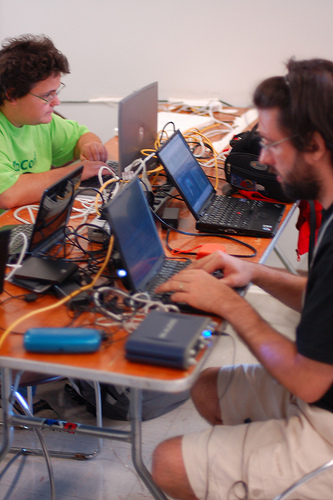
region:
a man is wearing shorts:
[282, 405, 296, 498]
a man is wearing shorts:
[224, 424, 262, 482]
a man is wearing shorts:
[218, 435, 242, 497]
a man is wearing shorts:
[228, 375, 292, 479]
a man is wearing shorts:
[250, 383, 273, 451]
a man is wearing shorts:
[215, 372, 241, 463]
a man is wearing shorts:
[236, 394, 275, 485]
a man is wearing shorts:
[222, 398, 254, 498]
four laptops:
[33, 66, 289, 365]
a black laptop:
[153, 125, 306, 252]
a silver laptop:
[86, 63, 207, 191]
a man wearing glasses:
[4, 21, 70, 118]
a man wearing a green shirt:
[1, 16, 103, 204]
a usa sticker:
[27, 398, 162, 486]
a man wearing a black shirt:
[242, 52, 330, 429]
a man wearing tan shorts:
[178, 93, 328, 492]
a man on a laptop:
[0, 57, 175, 191]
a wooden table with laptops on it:
[19, 106, 263, 382]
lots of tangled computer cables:
[72, 227, 137, 313]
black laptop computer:
[77, 166, 266, 322]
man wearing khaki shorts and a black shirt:
[131, 56, 332, 498]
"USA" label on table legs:
[25, 405, 86, 447]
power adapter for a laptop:
[151, 198, 272, 263]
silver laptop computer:
[83, 73, 172, 191]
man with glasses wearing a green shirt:
[0, 19, 122, 204]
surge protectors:
[87, 145, 185, 253]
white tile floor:
[12, 397, 205, 498]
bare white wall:
[88, 27, 267, 103]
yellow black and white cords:
[59, 137, 168, 284]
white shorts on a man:
[122, 336, 322, 499]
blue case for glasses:
[16, 319, 112, 360]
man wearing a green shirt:
[0, 90, 107, 210]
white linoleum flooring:
[57, 460, 129, 492]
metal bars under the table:
[0, 401, 164, 448]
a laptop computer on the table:
[88, 146, 273, 371]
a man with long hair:
[230, 48, 331, 219]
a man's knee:
[145, 418, 217, 498]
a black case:
[11, 244, 87, 299]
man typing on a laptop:
[111, 62, 330, 349]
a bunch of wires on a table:
[52, 193, 120, 313]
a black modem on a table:
[126, 303, 219, 372]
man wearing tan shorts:
[209, 349, 326, 483]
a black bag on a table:
[222, 133, 284, 195]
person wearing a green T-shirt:
[0, 117, 92, 192]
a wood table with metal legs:
[2, 345, 159, 492]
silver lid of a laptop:
[113, 84, 161, 181]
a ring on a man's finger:
[173, 277, 189, 294]